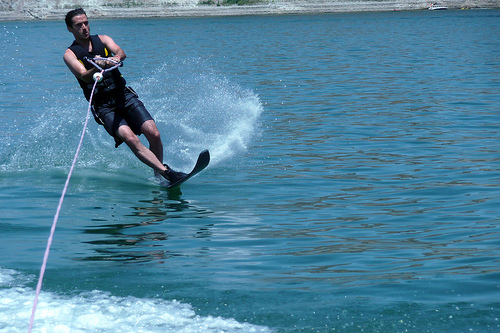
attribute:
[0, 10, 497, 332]
water — large, open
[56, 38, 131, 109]
vest — small, black, cloth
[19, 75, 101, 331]
purple line — long, thin